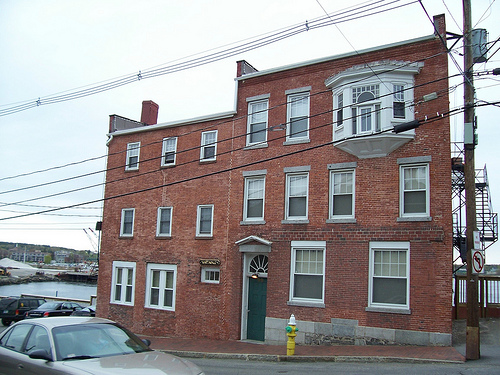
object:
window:
[247, 93, 271, 146]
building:
[93, 12, 454, 348]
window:
[285, 92, 314, 140]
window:
[242, 180, 265, 219]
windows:
[152, 205, 177, 239]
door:
[247, 275, 270, 343]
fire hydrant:
[285, 313, 297, 356]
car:
[0, 317, 210, 375]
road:
[0, 319, 500, 375]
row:
[0, 298, 95, 326]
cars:
[68, 305, 97, 317]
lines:
[253, 104, 278, 115]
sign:
[470, 249, 486, 273]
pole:
[460, 0, 481, 361]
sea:
[0, 275, 102, 299]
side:
[0, 296, 95, 322]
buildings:
[0, 241, 83, 261]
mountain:
[0, 241, 99, 261]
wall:
[94, 14, 451, 347]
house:
[96, 13, 454, 347]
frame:
[244, 92, 274, 148]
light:
[251, 273, 258, 280]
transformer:
[468, 26, 490, 65]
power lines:
[0, 0, 500, 224]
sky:
[0, 0, 500, 251]